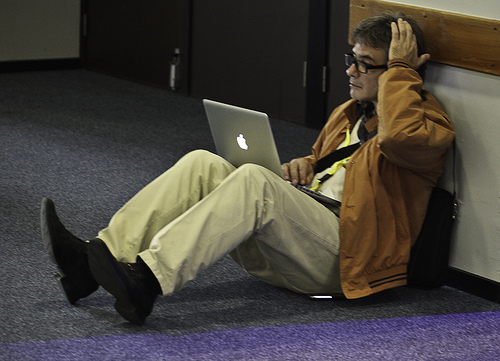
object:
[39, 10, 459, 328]
man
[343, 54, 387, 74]
glasses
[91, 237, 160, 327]
shoe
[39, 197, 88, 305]
shoe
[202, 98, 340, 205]
laptop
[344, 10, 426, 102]
head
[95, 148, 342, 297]
pants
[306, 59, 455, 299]
jacket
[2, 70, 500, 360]
carpet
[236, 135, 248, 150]
apple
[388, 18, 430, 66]
hand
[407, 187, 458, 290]
bag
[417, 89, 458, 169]
shoulders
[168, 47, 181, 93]
doorstopper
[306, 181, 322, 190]
idcard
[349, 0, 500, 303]
wall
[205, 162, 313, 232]
lap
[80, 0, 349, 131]
doorway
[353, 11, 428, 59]
hair